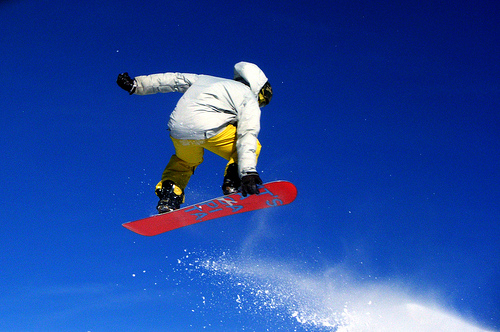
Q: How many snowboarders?
A: One.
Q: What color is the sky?
A: Blue.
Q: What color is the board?
A: Red and blue.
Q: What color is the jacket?
A: White.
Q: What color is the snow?
A: White.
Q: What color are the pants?
A: Yellow.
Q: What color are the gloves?
A: Black.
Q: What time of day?
A: Noon.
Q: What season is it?
A: Winter.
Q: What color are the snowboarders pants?
A: Yellow.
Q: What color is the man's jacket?
A: Light gray.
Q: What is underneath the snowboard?
A: Snow dust.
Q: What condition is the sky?
A: Clear and blue.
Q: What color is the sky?
A: Blue.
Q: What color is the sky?
A: Blue.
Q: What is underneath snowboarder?
A: Snow dust.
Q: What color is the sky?
A: Blue.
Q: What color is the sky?
A: Blue.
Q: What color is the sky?
A: Blue.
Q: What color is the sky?
A: Pitch blue.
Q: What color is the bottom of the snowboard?
A: Red.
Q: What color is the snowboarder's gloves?
A: Black.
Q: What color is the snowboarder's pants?
A: Yellow.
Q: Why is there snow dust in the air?
A: The snowboarder is doing a trick.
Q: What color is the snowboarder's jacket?
A: White.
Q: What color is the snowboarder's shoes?
A: Black.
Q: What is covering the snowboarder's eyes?
A: Shades.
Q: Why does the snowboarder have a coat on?
A: It's cold to him.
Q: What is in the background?
A: Blue clear sky.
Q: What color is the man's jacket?
A: Light grey.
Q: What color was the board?
A: Red.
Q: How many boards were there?
A: One.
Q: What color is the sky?
A: Blue.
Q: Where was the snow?
A: Under the board.